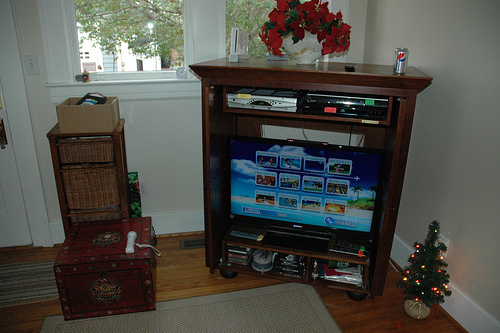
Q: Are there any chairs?
A: No, there are no chairs.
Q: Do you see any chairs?
A: No, there are no chairs.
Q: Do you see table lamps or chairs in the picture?
A: No, there are no chairs or table lamps.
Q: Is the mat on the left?
A: Yes, the mat is on the left of the image.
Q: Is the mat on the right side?
A: No, the mat is on the left of the image.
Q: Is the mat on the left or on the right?
A: The mat is on the left of the image.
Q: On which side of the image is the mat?
A: The mat is on the left of the image.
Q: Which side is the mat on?
A: The mat is on the left of the image.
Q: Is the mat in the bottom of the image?
A: Yes, the mat is in the bottom of the image.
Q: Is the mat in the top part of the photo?
A: No, the mat is in the bottom of the image.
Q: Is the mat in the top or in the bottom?
A: The mat is in the bottom of the image.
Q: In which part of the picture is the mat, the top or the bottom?
A: The mat is in the bottom of the image.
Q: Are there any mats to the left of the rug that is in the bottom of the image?
A: Yes, there is a mat to the left of the rug.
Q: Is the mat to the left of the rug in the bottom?
A: Yes, the mat is to the left of the rug.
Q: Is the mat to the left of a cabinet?
A: No, the mat is to the left of the rug.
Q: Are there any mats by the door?
A: Yes, there is a mat by the door.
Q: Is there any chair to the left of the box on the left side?
A: No, there is a mat to the left of the box.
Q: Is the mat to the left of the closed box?
A: Yes, the mat is to the left of the box.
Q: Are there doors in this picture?
A: Yes, there is a door.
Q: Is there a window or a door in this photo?
A: Yes, there is a door.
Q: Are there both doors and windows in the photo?
A: Yes, there are both a door and a window.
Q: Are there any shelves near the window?
A: Yes, there is a shelf near the window.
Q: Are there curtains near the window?
A: No, there is a shelf near the window.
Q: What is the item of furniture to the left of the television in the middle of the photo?
A: The piece of furniture is a shelf.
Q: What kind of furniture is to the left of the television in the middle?
A: The piece of furniture is a shelf.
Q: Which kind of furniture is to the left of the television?
A: The piece of furniture is a shelf.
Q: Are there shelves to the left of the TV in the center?
A: Yes, there is a shelf to the left of the television.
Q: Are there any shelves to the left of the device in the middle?
A: Yes, there is a shelf to the left of the television.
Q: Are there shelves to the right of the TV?
A: No, the shelf is to the left of the TV.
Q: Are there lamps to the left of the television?
A: No, there is a shelf to the left of the television.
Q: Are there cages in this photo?
A: No, there are no cages.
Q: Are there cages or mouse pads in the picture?
A: No, there are no cages or mouse pads.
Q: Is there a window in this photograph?
A: Yes, there is a window.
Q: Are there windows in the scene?
A: Yes, there is a window.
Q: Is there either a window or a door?
A: Yes, there is a window.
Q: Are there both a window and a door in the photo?
A: Yes, there are both a window and a door.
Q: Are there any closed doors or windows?
A: Yes, there is a closed window.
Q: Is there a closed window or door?
A: Yes, there is a closed window.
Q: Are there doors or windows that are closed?
A: Yes, the window is closed.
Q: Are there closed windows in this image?
A: Yes, there is a closed window.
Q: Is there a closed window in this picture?
A: Yes, there is a closed window.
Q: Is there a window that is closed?
A: Yes, there is a window that is closed.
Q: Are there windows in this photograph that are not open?
A: Yes, there is an closed window.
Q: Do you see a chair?
A: No, there are no chairs.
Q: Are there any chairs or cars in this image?
A: No, there are no chairs or cars.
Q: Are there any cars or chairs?
A: No, there are no chairs or cars.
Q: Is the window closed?
A: Yes, the window is closed.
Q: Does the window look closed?
A: Yes, the window is closed.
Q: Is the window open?
A: No, the window is closed.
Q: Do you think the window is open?
A: No, the window is closed.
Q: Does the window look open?
A: No, the window is closed.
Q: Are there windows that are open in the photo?
A: No, there is a window but it is closed.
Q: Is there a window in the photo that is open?
A: No, there is a window but it is closed.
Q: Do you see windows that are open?
A: No, there is a window but it is closed.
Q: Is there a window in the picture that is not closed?
A: No, there is a window but it is closed.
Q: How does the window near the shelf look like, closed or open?
A: The window is closed.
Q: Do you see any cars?
A: No, there are no cars.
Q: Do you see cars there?
A: No, there are no cars.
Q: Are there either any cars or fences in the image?
A: No, there are no cars or fences.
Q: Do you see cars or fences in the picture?
A: No, there are no cars or fences.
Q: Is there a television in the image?
A: Yes, there is a television.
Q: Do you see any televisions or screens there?
A: Yes, there is a television.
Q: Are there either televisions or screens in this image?
A: Yes, there is a television.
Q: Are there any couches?
A: No, there are no couches.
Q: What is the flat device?
A: The device is a television.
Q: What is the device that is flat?
A: The device is a television.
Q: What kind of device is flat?
A: The device is a television.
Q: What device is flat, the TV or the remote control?
A: The TV is flat.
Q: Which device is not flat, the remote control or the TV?
A: The remote control is not flat.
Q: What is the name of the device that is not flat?
A: The device is a remote control.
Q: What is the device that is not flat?
A: The device is a remote control.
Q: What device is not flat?
A: The device is a remote control.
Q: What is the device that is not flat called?
A: The device is a remote control.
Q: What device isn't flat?
A: The device is a remote control.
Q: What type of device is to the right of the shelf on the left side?
A: The device is a television.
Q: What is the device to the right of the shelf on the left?
A: The device is a television.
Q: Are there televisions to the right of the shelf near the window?
A: Yes, there is a television to the right of the shelf.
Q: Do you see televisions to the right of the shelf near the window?
A: Yes, there is a television to the right of the shelf.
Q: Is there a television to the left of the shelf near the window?
A: No, the television is to the right of the shelf.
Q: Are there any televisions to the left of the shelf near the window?
A: No, the television is to the right of the shelf.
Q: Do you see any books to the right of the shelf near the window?
A: No, there is a television to the right of the shelf.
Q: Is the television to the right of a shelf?
A: Yes, the television is to the right of a shelf.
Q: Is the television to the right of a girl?
A: No, the television is to the right of a shelf.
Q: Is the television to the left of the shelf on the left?
A: No, the television is to the right of the shelf.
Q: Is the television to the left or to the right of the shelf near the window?
A: The television is to the right of the shelf.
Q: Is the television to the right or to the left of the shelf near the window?
A: The television is to the right of the shelf.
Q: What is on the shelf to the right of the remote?
A: The television is on the shelf.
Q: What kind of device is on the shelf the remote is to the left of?
A: The device is a television.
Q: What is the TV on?
A: The TV is on the shelf.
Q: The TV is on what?
A: The TV is on the shelf.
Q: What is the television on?
A: The TV is on the shelf.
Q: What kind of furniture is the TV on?
A: The TV is on the shelf.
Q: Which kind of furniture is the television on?
A: The TV is on the shelf.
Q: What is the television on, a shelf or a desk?
A: The television is on a shelf.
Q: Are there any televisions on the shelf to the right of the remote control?
A: Yes, there is a television on the shelf.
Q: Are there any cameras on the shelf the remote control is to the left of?
A: No, there is a television on the shelf.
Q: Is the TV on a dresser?
A: No, the TV is on a shelf.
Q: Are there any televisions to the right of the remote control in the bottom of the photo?
A: Yes, there is a television to the right of the remote control.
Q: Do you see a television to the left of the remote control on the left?
A: No, the television is to the right of the remote.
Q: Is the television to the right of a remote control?
A: Yes, the television is to the right of a remote control.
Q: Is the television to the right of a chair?
A: No, the television is to the right of a remote control.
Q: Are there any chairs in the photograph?
A: No, there are no chairs.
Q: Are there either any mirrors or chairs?
A: No, there are no chairs or mirrors.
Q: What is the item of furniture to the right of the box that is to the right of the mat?
A: The piece of furniture is a shelf.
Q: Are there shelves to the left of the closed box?
A: No, the shelf is to the right of the box.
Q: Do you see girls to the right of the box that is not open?
A: No, there is a shelf to the right of the box.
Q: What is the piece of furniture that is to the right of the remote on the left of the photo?
A: The piece of furniture is a shelf.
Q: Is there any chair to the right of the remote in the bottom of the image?
A: No, there is a shelf to the right of the remote control.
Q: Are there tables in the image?
A: No, there are no tables.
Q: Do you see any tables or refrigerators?
A: No, there are no tables or refrigerators.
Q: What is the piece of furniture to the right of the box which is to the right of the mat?
A: The piece of furniture is a shelf.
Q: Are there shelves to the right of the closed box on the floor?
A: Yes, there is a shelf to the right of the box.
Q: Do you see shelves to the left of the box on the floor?
A: No, the shelf is to the right of the box.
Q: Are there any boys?
A: No, there are no boys.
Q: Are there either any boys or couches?
A: No, there are no boys or couches.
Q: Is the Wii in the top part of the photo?
A: Yes, the Wii is in the top of the image.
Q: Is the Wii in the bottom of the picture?
A: No, the Wii is in the top of the image.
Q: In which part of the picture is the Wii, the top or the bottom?
A: The Wii is in the top of the image.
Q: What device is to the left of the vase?
A: The device is a Wii.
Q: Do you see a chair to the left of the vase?
A: No, there is a Wii to the left of the vase.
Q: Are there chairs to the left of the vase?
A: No, there is a Wii to the left of the vase.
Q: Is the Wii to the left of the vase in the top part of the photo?
A: Yes, the Wii is to the left of the vase.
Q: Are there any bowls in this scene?
A: No, there are no bowls.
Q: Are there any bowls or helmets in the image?
A: No, there are no bowls or helmets.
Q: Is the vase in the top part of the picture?
A: Yes, the vase is in the top of the image.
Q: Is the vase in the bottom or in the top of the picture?
A: The vase is in the top of the image.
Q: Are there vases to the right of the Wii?
A: Yes, there is a vase to the right of the Wii.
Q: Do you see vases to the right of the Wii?
A: Yes, there is a vase to the right of the Wii.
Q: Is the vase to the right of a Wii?
A: Yes, the vase is to the right of a Wii.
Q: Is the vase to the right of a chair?
A: No, the vase is to the right of a Wii.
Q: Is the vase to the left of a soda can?
A: Yes, the vase is to the left of a soda can.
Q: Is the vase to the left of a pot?
A: No, the vase is to the left of a soda can.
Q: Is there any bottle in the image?
A: No, there are no bottles.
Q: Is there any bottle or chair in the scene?
A: No, there are no bottles or chairs.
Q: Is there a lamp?
A: No, there are no lamps.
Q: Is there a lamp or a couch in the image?
A: No, there are no lamps or couches.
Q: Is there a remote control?
A: Yes, there is a remote control.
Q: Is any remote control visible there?
A: Yes, there is a remote control.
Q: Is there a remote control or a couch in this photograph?
A: Yes, there is a remote control.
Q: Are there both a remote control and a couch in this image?
A: No, there is a remote control but no couches.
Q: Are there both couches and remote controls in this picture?
A: No, there is a remote control but no couches.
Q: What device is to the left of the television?
A: The device is a remote control.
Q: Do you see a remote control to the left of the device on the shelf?
A: Yes, there is a remote control to the left of the television.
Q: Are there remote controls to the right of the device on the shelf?
A: No, the remote control is to the left of the TV.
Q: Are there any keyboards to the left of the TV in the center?
A: No, there is a remote control to the left of the television.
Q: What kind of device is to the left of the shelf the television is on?
A: The device is a remote control.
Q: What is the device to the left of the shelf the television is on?
A: The device is a remote control.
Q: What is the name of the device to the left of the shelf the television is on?
A: The device is a remote control.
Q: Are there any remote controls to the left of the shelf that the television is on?
A: Yes, there is a remote control to the left of the shelf.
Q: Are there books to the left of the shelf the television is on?
A: No, there is a remote control to the left of the shelf.